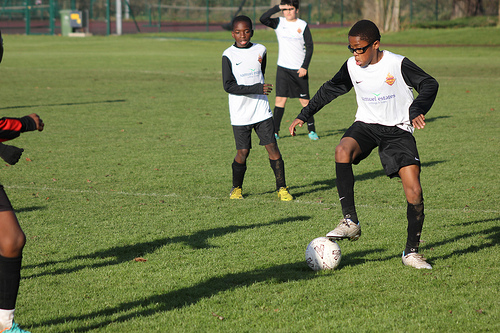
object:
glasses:
[347, 41, 381, 53]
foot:
[323, 218, 361, 237]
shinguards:
[402, 199, 425, 254]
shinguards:
[334, 163, 361, 224]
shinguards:
[267, 155, 287, 190]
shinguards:
[230, 158, 248, 188]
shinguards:
[270, 106, 286, 136]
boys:
[0, 27, 44, 332]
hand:
[256, 82, 275, 96]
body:
[221, 15, 294, 201]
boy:
[288, 19, 440, 268]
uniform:
[220, 42, 276, 150]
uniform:
[295, 50, 440, 178]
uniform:
[259, 4, 314, 100]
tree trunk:
[451, 1, 468, 19]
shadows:
[19, 215, 313, 279]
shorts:
[339, 120, 421, 179]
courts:
[0, 9, 499, 332]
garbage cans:
[59, 8, 84, 36]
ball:
[306, 236, 343, 273]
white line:
[0, 184, 499, 214]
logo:
[384, 74, 396, 86]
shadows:
[20, 247, 388, 332]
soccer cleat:
[306, 131, 319, 140]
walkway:
[1, 17, 361, 35]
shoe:
[274, 186, 295, 201]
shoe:
[228, 186, 244, 200]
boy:
[258, 0, 320, 141]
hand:
[277, 3, 293, 10]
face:
[282, 9, 297, 21]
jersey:
[294, 49, 438, 133]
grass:
[0, 28, 499, 331]